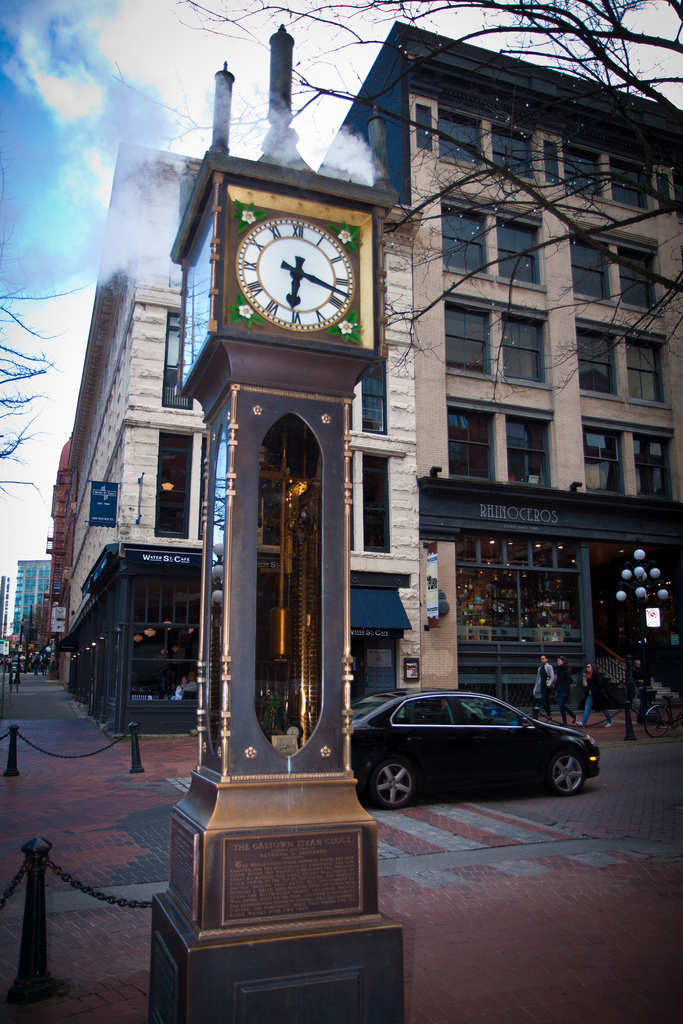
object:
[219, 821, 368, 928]
plaque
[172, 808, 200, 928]
plaque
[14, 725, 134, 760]
chain links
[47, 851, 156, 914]
chain links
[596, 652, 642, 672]
stairs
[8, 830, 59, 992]
post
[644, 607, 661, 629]
sign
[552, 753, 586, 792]
rim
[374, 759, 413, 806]
rim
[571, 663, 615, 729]
woman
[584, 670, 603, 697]
black jacket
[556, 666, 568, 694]
black jacket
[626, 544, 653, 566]
lights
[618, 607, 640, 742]
black pole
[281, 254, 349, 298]
hands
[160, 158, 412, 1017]
monument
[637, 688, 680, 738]
bicycle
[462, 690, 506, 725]
window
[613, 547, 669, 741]
street lamp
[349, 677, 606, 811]
vehicle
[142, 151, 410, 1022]
tower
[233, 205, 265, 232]
flower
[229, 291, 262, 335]
flower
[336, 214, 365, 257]
flower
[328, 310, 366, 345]
flower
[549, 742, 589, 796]
tires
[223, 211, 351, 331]
clock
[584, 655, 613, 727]
person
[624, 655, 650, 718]
person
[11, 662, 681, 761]
sidewalk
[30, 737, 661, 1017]
ground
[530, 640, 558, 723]
man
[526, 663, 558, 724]
outfit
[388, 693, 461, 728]
window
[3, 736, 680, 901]
street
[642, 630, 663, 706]
pole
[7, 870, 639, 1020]
sidewalk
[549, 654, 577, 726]
woman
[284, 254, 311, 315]
hands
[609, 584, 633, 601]
bulbs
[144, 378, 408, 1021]
pedastal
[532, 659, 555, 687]
jacket